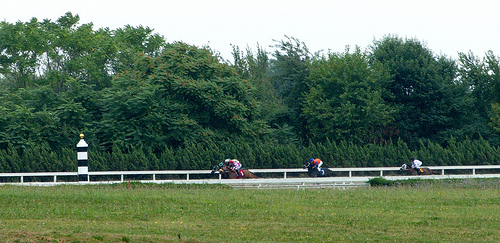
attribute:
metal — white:
[0, 162, 499, 184]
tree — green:
[291, 56, 388, 143]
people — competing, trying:
[225, 158, 242, 177]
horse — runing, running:
[211, 162, 257, 179]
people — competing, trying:
[309, 158, 324, 172]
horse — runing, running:
[300, 162, 329, 178]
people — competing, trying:
[407, 157, 423, 171]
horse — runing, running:
[399, 162, 432, 174]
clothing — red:
[313, 157, 322, 165]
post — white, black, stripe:
[76, 138, 89, 173]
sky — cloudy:
[2, 2, 498, 68]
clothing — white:
[412, 160, 424, 171]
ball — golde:
[77, 131, 87, 138]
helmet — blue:
[306, 157, 315, 167]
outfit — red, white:
[228, 159, 241, 172]